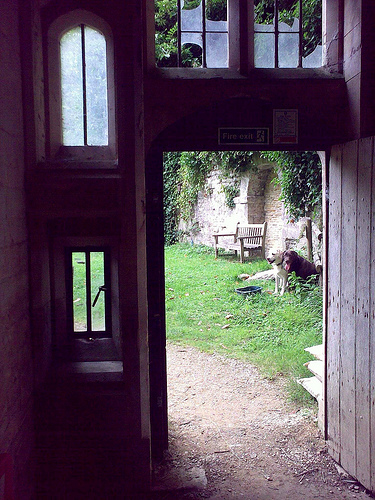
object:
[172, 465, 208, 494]
rocks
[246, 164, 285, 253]
arc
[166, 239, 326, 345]
yard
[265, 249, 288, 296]
canine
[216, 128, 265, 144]
sign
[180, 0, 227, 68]
glass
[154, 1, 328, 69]
window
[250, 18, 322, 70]
glass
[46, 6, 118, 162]
arched window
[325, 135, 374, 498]
door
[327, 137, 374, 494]
structure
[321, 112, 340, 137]
ground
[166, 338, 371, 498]
dirt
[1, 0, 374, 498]
building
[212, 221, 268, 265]
bench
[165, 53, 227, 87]
wall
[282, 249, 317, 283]
canine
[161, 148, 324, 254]
plant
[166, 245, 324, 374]
terrain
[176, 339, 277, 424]
dirt path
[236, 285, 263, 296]
container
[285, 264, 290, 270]
tongue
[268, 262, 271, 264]
tongue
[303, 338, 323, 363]
bag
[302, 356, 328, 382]
bag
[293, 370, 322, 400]
bag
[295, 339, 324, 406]
stack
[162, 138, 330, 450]
door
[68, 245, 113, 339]
window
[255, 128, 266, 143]
picture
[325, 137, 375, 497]
board wall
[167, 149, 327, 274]
wall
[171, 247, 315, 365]
space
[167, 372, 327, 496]
ground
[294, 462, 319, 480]
sticks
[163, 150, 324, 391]
outdoors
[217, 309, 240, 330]
leaves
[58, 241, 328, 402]
grass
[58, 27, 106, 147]
sunlight